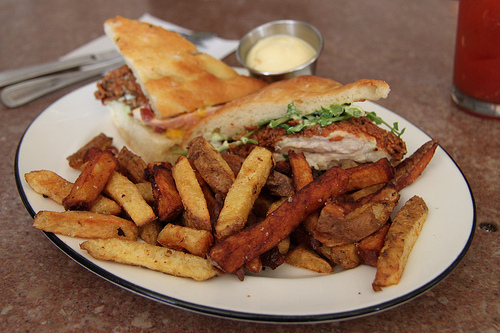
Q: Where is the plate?
A: Table.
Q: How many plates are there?
A: One.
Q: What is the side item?
A: Fries.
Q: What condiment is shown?
A: Mayo.